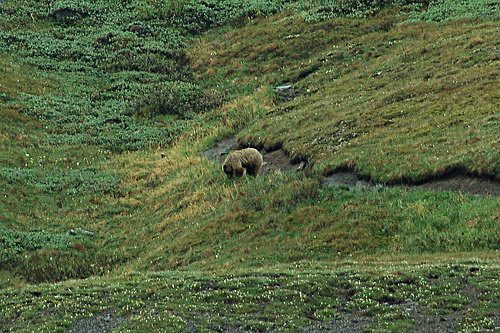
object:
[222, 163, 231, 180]
head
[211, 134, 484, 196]
trail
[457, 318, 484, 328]
flowers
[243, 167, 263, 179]
leg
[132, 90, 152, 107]
green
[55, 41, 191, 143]
bushes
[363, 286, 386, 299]
white flower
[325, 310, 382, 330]
gravel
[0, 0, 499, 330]
ground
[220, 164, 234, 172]
ear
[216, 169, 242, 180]
snout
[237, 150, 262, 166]
brown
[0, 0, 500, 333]
grass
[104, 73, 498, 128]
shrubs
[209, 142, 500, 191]
dirt path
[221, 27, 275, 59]
brown spots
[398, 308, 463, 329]
rocks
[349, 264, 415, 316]
small flowers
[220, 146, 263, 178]
bear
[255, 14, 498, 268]
hill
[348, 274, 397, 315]
flowers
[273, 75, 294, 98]
rock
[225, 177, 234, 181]
food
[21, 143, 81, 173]
clover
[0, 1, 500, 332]
field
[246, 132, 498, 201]
patch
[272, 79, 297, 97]
something